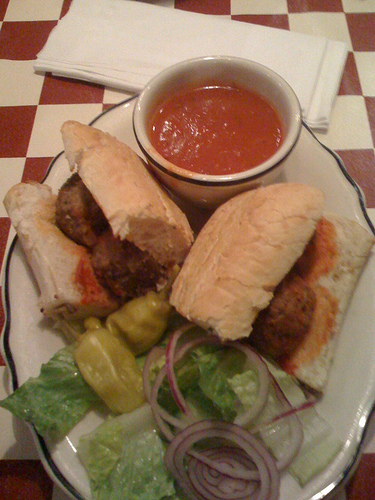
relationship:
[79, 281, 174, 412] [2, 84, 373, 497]
peppers on plate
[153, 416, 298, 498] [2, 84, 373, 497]
onions on plate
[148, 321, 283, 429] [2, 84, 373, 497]
onions on plate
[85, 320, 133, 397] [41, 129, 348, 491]
jalapeno on plate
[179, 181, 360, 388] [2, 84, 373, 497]
bread on plate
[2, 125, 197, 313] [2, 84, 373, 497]
half sandwich on plate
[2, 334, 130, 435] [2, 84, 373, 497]
lettuce slice on plate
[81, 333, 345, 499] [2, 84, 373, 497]
lettuce slice on plate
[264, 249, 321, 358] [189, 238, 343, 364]
meatball in sandwich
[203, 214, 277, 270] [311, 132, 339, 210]
bread on plate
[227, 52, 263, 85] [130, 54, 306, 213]
part of cup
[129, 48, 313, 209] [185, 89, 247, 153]
bowl of sauce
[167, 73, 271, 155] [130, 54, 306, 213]
sauce in cup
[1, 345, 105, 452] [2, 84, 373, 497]
lettuce on plate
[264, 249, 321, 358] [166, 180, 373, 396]
meatball in bread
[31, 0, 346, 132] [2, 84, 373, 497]
napkin next to plate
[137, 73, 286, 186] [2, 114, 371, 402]
sauce next to meatball sandwich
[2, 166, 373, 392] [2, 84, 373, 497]
sandwich on plate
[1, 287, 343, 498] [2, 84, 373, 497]
salad on plate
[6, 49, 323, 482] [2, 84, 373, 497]
food on plate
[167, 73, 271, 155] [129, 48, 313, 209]
sauce in bowl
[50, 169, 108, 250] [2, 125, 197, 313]
meatball on half sandwich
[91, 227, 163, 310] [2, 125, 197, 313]
meatball on half sandwich